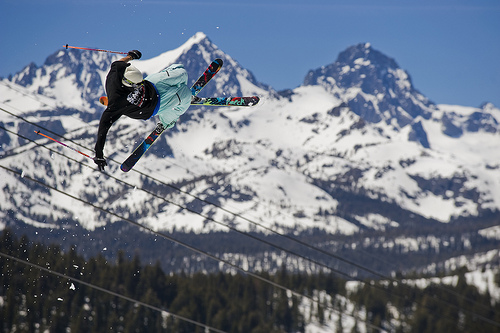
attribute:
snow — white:
[133, 131, 347, 236]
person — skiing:
[89, 47, 198, 169]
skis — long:
[116, 58, 266, 173]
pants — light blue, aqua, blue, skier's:
[146, 60, 196, 129]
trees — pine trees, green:
[0, 217, 499, 328]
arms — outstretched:
[89, 43, 153, 179]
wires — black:
[5, 143, 499, 333]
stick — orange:
[97, 94, 110, 111]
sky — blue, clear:
[0, 2, 496, 37]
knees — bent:
[169, 60, 199, 107]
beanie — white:
[119, 63, 150, 91]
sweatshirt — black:
[92, 59, 162, 155]